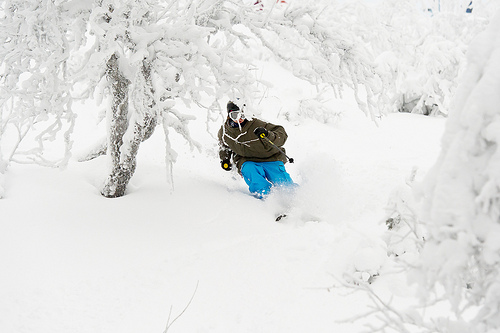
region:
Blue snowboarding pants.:
[225, 160, 323, 196]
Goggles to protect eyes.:
[226, 109, 251, 120]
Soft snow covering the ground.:
[16, 180, 465, 331]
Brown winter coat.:
[214, 127, 297, 161]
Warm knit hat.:
[27, 17, 313, 95]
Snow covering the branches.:
[22, 2, 340, 91]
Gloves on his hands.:
[252, 125, 272, 142]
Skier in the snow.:
[209, 97, 306, 220]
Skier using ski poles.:
[221, 140, 308, 169]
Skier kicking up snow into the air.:
[257, 183, 326, 228]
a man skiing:
[206, 101, 298, 226]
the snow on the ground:
[55, 232, 175, 329]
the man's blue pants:
[233, 165, 320, 200]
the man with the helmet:
[220, 101, 259, 118]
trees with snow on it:
[77, 46, 191, 199]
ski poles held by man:
[253, 129, 303, 163]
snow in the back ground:
[320, 42, 435, 109]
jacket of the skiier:
[226, 134, 298, 156]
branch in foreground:
[135, 290, 241, 330]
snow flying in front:
[263, 190, 297, 217]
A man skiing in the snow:
[209, 90, 316, 230]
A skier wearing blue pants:
[210, 95, 302, 204]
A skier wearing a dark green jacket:
[207, 97, 299, 195]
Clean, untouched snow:
[0, 199, 170, 309]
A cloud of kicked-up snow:
[257, 160, 354, 219]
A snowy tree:
[2, 0, 277, 205]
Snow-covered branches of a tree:
[0, 4, 111, 96]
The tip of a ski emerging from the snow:
[257, 195, 301, 224]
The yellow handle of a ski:
[214, 155, 236, 172]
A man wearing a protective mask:
[219, 99, 257, 129]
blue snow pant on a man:
[236, 155, 308, 200]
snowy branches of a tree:
[165, 84, 202, 148]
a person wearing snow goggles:
[227, 109, 249, 121]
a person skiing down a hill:
[213, 78, 329, 232]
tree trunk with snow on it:
[91, 92, 129, 203]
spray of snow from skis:
[241, 172, 360, 237]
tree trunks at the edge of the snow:
[391, 102, 437, 121]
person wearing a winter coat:
[218, 127, 292, 162]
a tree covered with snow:
[390, 138, 499, 253]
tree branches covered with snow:
[16, 32, 80, 110]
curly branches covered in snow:
[20, 22, 83, 183]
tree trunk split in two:
[46, 20, 171, 205]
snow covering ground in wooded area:
[16, 125, 196, 311]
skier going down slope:
[187, 91, 337, 236]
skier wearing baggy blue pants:
[230, 152, 310, 227]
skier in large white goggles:
[216, 95, 256, 122]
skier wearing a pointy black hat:
[217, 91, 247, 122]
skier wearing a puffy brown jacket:
[210, 100, 290, 170]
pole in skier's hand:
[251, 120, 296, 167]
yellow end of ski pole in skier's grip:
[207, 152, 234, 173]